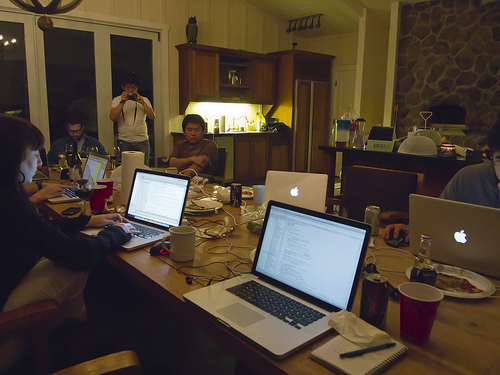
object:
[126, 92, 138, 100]
camera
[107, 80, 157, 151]
blue sky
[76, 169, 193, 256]
laptop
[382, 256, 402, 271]
table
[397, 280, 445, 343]
cup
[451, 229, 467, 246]
logo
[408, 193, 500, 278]
laptop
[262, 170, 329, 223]
laptop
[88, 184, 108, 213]
cup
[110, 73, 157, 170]
he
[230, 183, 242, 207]
can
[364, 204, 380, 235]
can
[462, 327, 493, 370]
table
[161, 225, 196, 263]
mug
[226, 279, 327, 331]
keyboard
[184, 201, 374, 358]
laptop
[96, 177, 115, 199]
cup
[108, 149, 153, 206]
paper towels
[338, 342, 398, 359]
ink pen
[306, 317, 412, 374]
notepad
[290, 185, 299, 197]
apple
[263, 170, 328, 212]
computer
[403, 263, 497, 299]
paper plate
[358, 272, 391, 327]
can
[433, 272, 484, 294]
pizza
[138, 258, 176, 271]
table